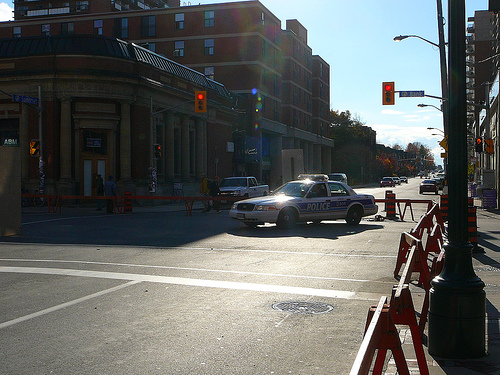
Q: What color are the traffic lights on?
A: Red.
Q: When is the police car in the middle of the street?
A: Daytime.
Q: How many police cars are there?
A: One.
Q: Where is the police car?
A: The street.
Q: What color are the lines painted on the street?
A: White.